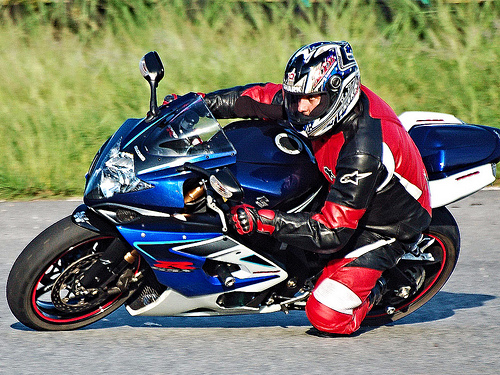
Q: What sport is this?
A: Motocross.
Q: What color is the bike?
A: Blue and white.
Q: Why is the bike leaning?
A: Turning.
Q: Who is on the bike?
A: Rider.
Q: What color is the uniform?
A: Red and black.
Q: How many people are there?
A: One.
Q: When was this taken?
A: During the day.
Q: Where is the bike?
A: On the road.